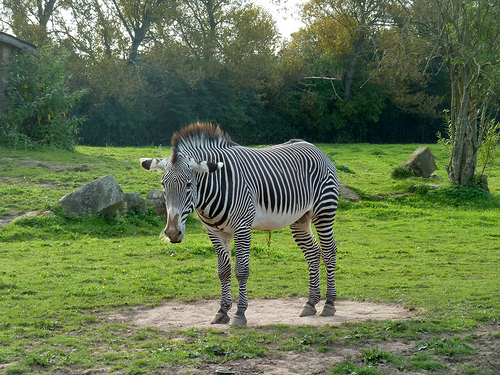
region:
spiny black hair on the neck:
[177, 123, 222, 136]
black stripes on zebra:
[251, 160, 300, 200]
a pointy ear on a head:
[192, 154, 229, 168]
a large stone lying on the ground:
[63, 169, 133, 231]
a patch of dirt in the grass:
[249, 301, 295, 324]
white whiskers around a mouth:
[160, 230, 174, 244]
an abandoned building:
[0, 31, 46, 129]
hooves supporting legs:
[201, 300, 245, 320]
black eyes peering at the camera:
[150, 174, 196, 193]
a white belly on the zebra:
[256, 205, 301, 231]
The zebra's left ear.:
[136, 155, 168, 179]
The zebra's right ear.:
[190, 157, 221, 172]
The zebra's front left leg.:
[204, 232, 230, 325]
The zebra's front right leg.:
[228, 225, 260, 322]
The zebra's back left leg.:
[289, 219, 321, 315]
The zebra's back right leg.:
[315, 207, 345, 314]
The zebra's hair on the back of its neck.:
[160, 114, 238, 153]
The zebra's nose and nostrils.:
[165, 223, 185, 244]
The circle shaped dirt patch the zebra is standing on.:
[122, 293, 427, 327]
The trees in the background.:
[7, 3, 499, 128]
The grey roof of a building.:
[0, 27, 38, 57]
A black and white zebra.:
[138, 123, 341, 328]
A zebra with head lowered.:
[139, 143, 221, 244]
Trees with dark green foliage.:
[93, 80, 386, 139]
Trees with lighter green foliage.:
[64, 0, 498, 79]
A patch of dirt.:
[141, 297, 416, 326]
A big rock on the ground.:
[53, 174, 162, 221]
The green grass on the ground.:
[383, 198, 498, 303]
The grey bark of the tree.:
[444, 95, 494, 185]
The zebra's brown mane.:
[163, 123, 240, 138]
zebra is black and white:
[147, 117, 374, 365]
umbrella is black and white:
[139, 108, 365, 343]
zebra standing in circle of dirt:
[102, 111, 437, 346]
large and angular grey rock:
[50, 160, 140, 245]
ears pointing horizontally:
[130, 150, 230, 170]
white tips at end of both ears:
[130, 152, 230, 174]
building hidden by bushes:
[0, 21, 72, 156]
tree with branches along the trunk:
[420, 25, 491, 195]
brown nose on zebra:
[150, 195, 185, 250]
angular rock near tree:
[386, 121, 486, 207]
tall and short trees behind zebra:
[100, 10, 416, 155]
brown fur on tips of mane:
[162, 117, 227, 167]